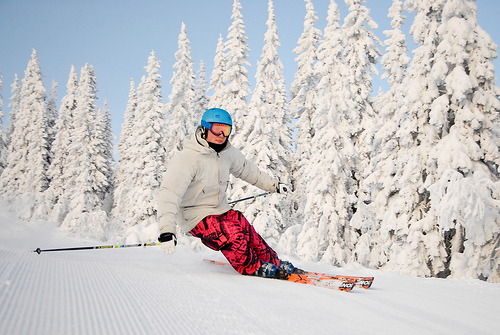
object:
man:
[152, 103, 299, 281]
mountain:
[2, 208, 498, 335]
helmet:
[201, 107, 234, 128]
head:
[202, 108, 234, 148]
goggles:
[207, 123, 232, 136]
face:
[207, 121, 231, 144]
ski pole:
[32, 235, 176, 256]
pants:
[187, 209, 297, 282]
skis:
[203, 256, 371, 291]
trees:
[403, 0, 494, 281]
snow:
[0, 217, 498, 333]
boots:
[258, 258, 284, 279]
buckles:
[275, 259, 292, 273]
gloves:
[157, 231, 177, 255]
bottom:
[4, 156, 50, 198]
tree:
[7, 42, 52, 212]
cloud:
[44, 73, 69, 100]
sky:
[0, 0, 498, 143]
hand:
[157, 232, 179, 255]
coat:
[156, 131, 278, 237]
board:
[194, 254, 354, 293]